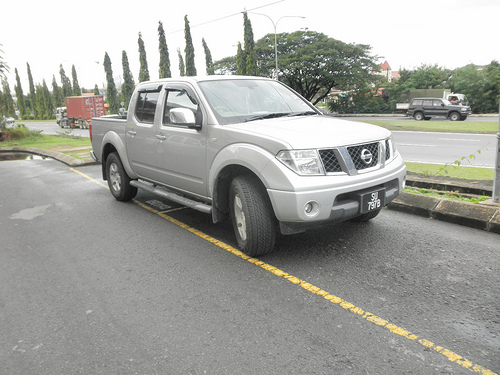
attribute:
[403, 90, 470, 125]
suv — black, parked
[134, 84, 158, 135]
window — rear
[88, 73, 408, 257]
truck — gray, large, silver, metal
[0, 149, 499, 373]
road — gray, tarmac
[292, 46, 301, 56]
leaf — green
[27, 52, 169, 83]
trees — tall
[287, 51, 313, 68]
leaf — green